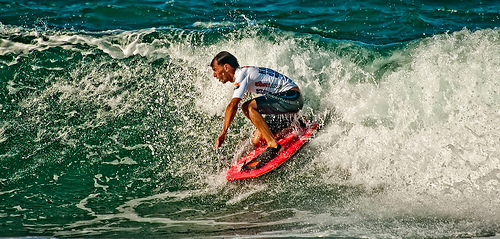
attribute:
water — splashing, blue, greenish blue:
[2, 4, 497, 237]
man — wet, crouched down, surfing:
[207, 49, 324, 165]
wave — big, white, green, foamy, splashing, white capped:
[1, 25, 499, 226]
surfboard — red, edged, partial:
[227, 110, 332, 179]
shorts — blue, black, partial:
[256, 88, 305, 115]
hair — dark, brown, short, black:
[208, 51, 238, 70]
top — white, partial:
[227, 66, 298, 107]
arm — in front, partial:
[215, 66, 246, 147]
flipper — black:
[239, 143, 285, 171]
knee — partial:
[241, 99, 257, 116]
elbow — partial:
[223, 100, 241, 112]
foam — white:
[195, 30, 490, 213]